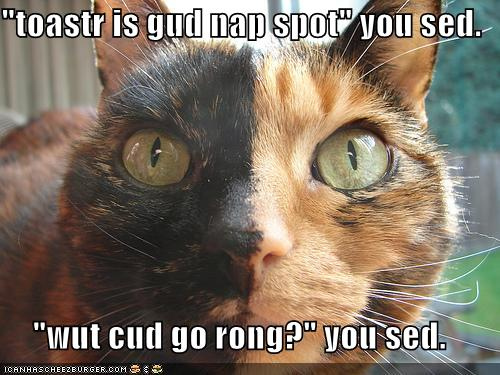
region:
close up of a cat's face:
[42, 3, 474, 374]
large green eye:
[312, 119, 393, 196]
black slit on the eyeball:
[342, 139, 359, 175]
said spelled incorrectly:
[382, 318, 436, 355]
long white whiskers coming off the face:
[348, 251, 499, 365]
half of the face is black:
[61, 46, 253, 369]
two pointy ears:
[82, 5, 464, 118]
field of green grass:
[432, 240, 499, 311]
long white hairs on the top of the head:
[324, 7, 495, 103]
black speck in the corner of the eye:
[308, 170, 318, 190]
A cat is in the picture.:
[3, 0, 495, 364]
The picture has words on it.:
[2, 2, 492, 57]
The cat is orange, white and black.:
[39, 2, 476, 363]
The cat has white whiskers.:
[330, 243, 495, 340]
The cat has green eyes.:
[98, 81, 413, 233]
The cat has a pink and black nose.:
[198, 198, 305, 298]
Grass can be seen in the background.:
[440, 245, 499, 330]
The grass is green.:
[435, 251, 499, 331]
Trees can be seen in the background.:
[431, 4, 494, 144]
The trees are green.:
[432, 0, 499, 138]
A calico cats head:
[53, 52, 471, 352]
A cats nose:
[198, 230, 300, 295]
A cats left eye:
[308, 102, 399, 208]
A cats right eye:
[94, 120, 199, 209]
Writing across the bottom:
[32, 316, 464, 354]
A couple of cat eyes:
[79, 93, 435, 203]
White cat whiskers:
[331, 231, 488, 323]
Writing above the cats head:
[12, 9, 488, 49]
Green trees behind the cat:
[428, 13, 498, 139]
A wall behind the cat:
[7, 20, 84, 109]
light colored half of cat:
[258, 47, 468, 319]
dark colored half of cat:
[44, 3, 251, 325]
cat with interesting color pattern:
[13, 43, 486, 315]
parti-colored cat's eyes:
[107, 110, 407, 204]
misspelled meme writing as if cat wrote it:
[1, 5, 468, 355]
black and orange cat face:
[29, 52, 470, 328]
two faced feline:
[38, 42, 475, 320]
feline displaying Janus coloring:
[28, 49, 480, 317]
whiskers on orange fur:
[342, 242, 498, 319]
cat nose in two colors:
[207, 182, 299, 291]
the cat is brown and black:
[10, 4, 449, 363]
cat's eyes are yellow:
[118, 92, 402, 211]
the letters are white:
[25, 304, 497, 363]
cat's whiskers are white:
[46, 243, 491, 365]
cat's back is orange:
[14, 88, 114, 370]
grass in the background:
[430, 205, 498, 337]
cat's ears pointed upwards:
[87, 0, 429, 108]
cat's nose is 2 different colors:
[192, 191, 324, 287]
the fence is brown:
[439, 112, 498, 254]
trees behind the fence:
[421, 0, 498, 151]